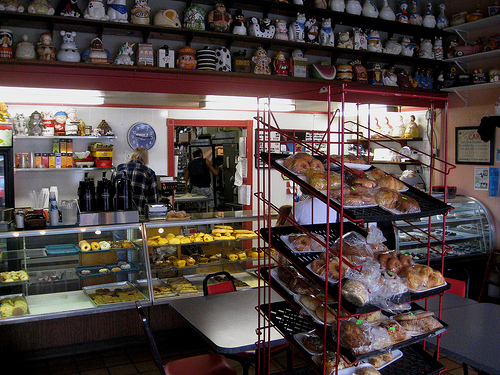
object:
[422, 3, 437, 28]
jars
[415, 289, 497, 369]
tables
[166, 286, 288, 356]
tables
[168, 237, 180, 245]
cookie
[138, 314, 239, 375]
chair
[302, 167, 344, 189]
bagels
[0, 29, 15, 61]
package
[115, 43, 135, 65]
jar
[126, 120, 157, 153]
wall clock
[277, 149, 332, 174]
bagels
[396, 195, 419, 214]
pastries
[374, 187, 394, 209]
pastries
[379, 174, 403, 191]
pastries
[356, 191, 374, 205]
pastries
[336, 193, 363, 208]
pastries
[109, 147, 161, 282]
person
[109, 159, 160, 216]
plaid shirt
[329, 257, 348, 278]
donut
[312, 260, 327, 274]
donut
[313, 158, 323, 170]
donut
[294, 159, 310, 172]
donut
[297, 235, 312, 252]
donut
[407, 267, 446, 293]
bread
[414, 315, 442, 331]
pastries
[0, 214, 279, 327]
shelf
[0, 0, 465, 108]
shelf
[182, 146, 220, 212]
man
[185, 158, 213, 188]
shirt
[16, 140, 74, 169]
tea boxes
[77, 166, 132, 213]
coffee dispensers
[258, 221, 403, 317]
trays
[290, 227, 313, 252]
donuts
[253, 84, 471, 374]
shelf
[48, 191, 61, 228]
cups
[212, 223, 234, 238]
donuts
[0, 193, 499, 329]
display case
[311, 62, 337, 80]
cookie jar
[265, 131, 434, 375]
cart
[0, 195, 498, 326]
counter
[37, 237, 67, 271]
glass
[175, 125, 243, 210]
room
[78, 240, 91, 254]
pastry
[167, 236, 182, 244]
pastry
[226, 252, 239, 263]
pastry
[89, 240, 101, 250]
pastry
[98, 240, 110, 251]
pastry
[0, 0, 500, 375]
bakery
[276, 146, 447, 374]
baked goods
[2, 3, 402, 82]
various items